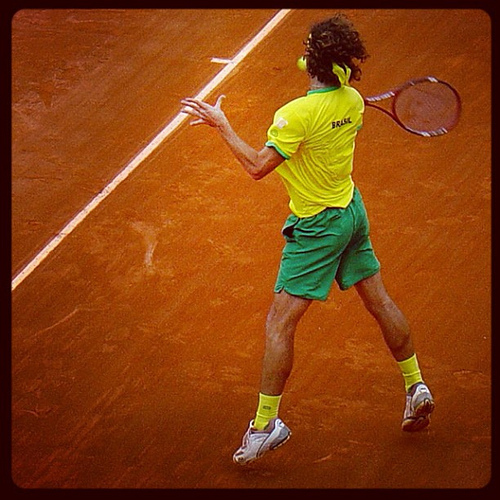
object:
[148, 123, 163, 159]
line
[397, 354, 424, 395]
socks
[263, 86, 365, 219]
shirt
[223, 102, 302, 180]
left arm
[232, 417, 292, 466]
sneaker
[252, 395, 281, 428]
sock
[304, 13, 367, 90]
head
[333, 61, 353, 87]
headband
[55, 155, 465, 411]
footprints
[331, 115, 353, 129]
black lettering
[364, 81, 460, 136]
racket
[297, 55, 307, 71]
ball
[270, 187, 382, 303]
shorts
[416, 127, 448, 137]
stripes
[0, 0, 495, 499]
court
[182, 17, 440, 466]
man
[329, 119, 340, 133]
letters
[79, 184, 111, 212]
lines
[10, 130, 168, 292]
dirt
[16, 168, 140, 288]
line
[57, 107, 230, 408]
ground